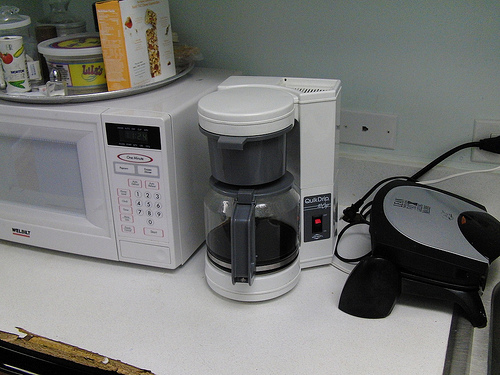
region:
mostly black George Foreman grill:
[335, 139, 499, 330]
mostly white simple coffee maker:
[196, 65, 343, 309]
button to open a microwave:
[115, 238, 177, 271]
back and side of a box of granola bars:
[93, 0, 180, 95]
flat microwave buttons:
[107, 148, 179, 243]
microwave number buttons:
[131, 187, 165, 228]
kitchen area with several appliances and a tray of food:
[0, 0, 499, 374]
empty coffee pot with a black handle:
[199, 173, 307, 285]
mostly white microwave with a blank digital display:
[0, 66, 243, 273]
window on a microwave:
[0, 133, 90, 215]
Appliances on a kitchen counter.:
[17, 16, 485, 366]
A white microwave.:
[1, 99, 208, 269]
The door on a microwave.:
[4, 112, 106, 233]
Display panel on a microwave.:
[103, 121, 165, 149]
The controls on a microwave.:
[108, 154, 167, 246]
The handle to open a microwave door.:
[114, 237, 174, 265]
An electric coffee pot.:
[190, 60, 340, 309]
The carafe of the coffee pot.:
[201, 175, 301, 281]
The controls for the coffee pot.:
[303, 188, 337, 243]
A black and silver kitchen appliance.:
[332, 153, 494, 322]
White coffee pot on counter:
[197, 62, 342, 319]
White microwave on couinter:
[0, 49, 220, 263]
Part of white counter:
[349, 342, 382, 372]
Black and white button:
[130, 186, 144, 204]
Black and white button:
[140, 189, 151, 199]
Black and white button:
[150, 188, 165, 200]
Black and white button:
[148, 197, 166, 210]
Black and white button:
[143, 212, 160, 227]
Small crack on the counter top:
[3, 311, 90, 371]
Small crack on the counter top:
[63, 338, 132, 371]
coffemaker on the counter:
[183, 62, 368, 357]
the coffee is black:
[204, 220, 308, 278]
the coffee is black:
[194, 156, 316, 296]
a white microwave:
[3, 75, 203, 275]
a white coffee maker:
[181, 53, 343, 311]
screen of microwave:
[100, 113, 161, 151]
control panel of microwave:
[105, 145, 166, 242]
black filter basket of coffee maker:
[200, 129, 288, 190]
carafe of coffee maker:
[195, 181, 295, 272]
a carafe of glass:
[197, 182, 304, 282]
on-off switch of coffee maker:
[310, 211, 325, 231]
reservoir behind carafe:
[301, 90, 346, 187]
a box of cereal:
[89, 5, 184, 91]